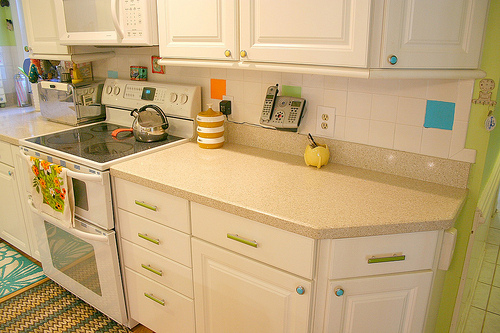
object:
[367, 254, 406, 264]
green handle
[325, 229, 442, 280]
drawer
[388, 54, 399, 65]
blue knob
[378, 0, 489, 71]
cupboard door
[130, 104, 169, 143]
tea kettle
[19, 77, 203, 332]
stove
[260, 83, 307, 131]
telephone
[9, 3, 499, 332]
wall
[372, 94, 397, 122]
tile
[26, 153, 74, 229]
towel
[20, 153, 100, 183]
oven door handle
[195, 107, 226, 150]
container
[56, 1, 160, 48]
microwave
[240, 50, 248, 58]
yellow knob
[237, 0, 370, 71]
cupboard door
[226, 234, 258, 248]
handle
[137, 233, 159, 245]
handle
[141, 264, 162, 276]
handle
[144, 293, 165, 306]
handle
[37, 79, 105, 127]
bread box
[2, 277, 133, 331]
rug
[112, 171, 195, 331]
cabinet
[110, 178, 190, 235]
drawers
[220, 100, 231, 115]
phone plug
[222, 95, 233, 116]
outlet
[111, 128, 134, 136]
spoon rest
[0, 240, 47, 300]
floor mat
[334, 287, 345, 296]
blue knob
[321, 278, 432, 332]
cabinet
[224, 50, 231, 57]
yellow knob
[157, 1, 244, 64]
cabinet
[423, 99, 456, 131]
blue paper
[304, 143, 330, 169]
yellow vase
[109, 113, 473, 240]
countertop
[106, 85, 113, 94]
white knob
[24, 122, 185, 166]
black top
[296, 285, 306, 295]
blue knob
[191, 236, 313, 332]
cabinet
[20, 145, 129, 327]
two doors